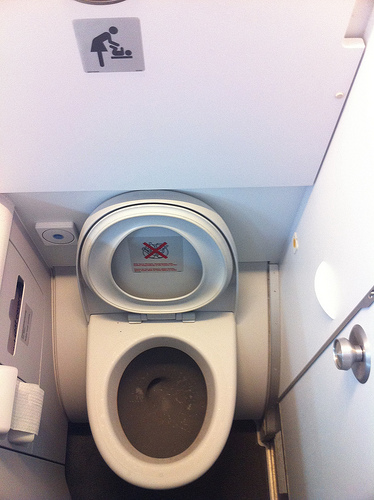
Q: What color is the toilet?
A: White.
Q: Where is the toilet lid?
A: Up.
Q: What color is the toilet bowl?
A: White.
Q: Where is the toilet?
A: A small space.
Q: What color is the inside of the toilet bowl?
A: Gray.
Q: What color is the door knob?
A: Silver.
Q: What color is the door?
A: White.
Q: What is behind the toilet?
A: A pullout table for infants.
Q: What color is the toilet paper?
A: White.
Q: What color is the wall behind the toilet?
A: White.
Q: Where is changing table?
A: Above commode.